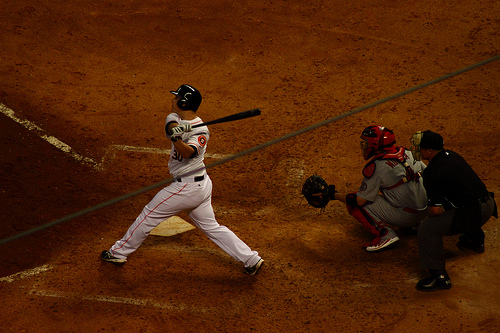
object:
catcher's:
[305, 125, 417, 251]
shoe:
[368, 229, 406, 255]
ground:
[9, 6, 497, 326]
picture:
[3, 4, 500, 329]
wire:
[6, 55, 496, 234]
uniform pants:
[116, 178, 258, 267]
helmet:
[165, 86, 203, 112]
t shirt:
[162, 116, 221, 172]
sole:
[368, 237, 402, 250]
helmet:
[362, 122, 405, 160]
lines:
[3, 99, 318, 317]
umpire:
[411, 129, 496, 312]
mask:
[411, 132, 426, 154]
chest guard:
[363, 152, 405, 179]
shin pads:
[345, 199, 383, 238]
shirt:
[363, 162, 428, 209]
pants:
[368, 199, 426, 233]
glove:
[298, 178, 348, 205]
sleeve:
[360, 164, 381, 204]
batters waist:
[172, 153, 216, 179]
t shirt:
[426, 152, 485, 210]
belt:
[460, 191, 490, 211]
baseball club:
[98, 66, 490, 305]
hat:
[409, 129, 443, 151]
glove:
[172, 125, 198, 136]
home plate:
[139, 215, 195, 236]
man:
[104, 83, 264, 272]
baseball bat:
[166, 105, 264, 139]